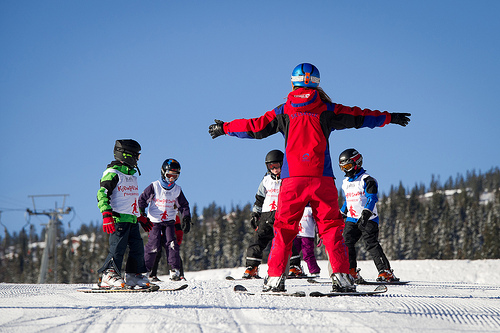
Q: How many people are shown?
A: 6.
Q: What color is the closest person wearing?
A: Red and black.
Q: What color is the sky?
A: Blue.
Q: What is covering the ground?
A: Snow.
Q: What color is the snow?
A: White.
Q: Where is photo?
A: None.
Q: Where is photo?
A: None.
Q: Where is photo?
A: None.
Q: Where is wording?
A: On ad.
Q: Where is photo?
A: No photo.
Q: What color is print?
A: Gray.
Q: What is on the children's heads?
A: Helmets.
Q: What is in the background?
A: Trees.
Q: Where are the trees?
A: Mountain.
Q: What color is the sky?
A: Blue.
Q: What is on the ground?
A: Snow.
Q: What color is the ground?
A: White.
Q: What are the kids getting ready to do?
A: Ski.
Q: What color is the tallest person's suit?
A: Red.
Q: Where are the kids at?
A: Ski resort.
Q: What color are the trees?
A: Green.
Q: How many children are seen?
A: Four.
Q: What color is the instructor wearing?
A: Red.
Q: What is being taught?
A: Skiing.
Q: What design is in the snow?
A: Lines.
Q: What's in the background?
A: Trees.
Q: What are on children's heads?
A: Helmets.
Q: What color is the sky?
A: Blue.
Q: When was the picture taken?
A: Daytime.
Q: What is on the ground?
A: Snow.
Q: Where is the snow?
A: On the ground.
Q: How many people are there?
A: Six.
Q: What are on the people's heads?
A: Helmets.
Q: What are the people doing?
A: Skiing.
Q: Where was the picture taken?
A: On snow.